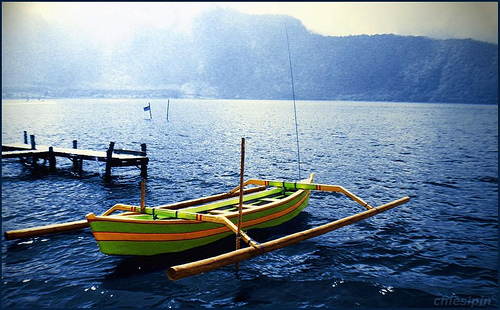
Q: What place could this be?
A: It is a lake.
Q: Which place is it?
A: It is a lake.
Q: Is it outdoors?
A: Yes, it is outdoors.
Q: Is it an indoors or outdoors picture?
A: It is outdoors.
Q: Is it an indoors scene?
A: No, it is outdoors.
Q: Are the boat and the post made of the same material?
A: Yes, both the boat and the post are made of wood.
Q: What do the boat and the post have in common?
A: The material, both the boat and the post are wooden.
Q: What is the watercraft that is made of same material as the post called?
A: The watercraft is a boat.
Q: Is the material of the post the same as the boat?
A: Yes, both the post and the boat are made of wood.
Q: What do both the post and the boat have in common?
A: The material, both the post and the boat are wooden.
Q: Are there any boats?
A: Yes, there is a boat.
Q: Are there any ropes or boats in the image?
A: Yes, there is a boat.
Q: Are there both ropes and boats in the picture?
A: No, there is a boat but no ropes.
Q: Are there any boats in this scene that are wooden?
A: Yes, there is a wood boat.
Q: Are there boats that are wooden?
A: Yes, there is a boat that is wooden.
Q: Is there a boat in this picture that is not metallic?
A: Yes, there is a wooden boat.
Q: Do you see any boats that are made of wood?
A: Yes, there is a boat that is made of wood.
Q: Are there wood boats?
A: Yes, there is a boat that is made of wood.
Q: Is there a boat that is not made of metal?
A: Yes, there is a boat that is made of wood.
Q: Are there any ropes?
A: No, there are no ropes.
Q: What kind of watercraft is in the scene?
A: The watercraft is a boat.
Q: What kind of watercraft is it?
A: The watercraft is a boat.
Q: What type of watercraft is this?
A: This is a boat.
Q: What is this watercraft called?
A: This is a boat.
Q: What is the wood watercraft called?
A: The watercraft is a boat.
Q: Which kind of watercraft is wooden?
A: The watercraft is a boat.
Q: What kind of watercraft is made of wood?
A: The watercraft is a boat.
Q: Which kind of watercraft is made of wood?
A: The watercraft is a boat.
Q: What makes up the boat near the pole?
A: The boat is made of wood.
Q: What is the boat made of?
A: The boat is made of wood.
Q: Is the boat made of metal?
A: No, the boat is made of wood.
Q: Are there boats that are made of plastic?
A: No, there is a boat but it is made of wood.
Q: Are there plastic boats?
A: No, there is a boat but it is made of wood.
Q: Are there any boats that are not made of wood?
A: No, there is a boat but it is made of wood.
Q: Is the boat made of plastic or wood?
A: The boat is made of wood.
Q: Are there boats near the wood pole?
A: Yes, there is a boat near the pole.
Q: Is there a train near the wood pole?
A: No, there is a boat near the pole.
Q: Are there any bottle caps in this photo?
A: No, there are no bottle caps.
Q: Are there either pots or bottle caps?
A: No, there are no bottle caps or pots.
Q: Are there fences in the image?
A: No, there are no fences.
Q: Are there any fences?
A: No, there are no fences.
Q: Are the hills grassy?
A: Yes, the hills are grassy.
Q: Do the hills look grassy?
A: Yes, the hills are grassy.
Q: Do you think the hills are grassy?
A: Yes, the hills are grassy.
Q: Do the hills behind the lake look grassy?
A: Yes, the hills are grassy.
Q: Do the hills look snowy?
A: No, the hills are grassy.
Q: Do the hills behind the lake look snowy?
A: No, the hills are grassy.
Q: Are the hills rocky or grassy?
A: The hills are grassy.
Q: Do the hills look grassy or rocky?
A: The hills are grassy.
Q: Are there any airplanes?
A: No, there are no airplanes.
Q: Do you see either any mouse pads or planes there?
A: No, there are no planes or mouse pads.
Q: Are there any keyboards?
A: No, there are no keyboards.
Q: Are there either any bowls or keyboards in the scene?
A: No, there are no keyboards or bowls.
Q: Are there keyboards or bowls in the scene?
A: No, there are no keyboards or bowls.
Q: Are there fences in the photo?
A: No, there are no fences.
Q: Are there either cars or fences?
A: No, there are no fences or cars.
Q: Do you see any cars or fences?
A: No, there are no fences or cars.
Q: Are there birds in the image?
A: No, there are no birds.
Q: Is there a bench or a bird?
A: No, there are no birds or benches.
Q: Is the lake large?
A: Yes, the lake is large.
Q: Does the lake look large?
A: Yes, the lake is large.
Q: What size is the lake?
A: The lake is large.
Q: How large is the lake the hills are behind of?
A: The lake is large.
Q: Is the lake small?
A: No, the lake is large.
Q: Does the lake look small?
A: No, the lake is large.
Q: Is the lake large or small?
A: The lake is large.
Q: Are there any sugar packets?
A: No, there are no sugar packets.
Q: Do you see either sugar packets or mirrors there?
A: No, there are no sugar packets or mirrors.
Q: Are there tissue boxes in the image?
A: No, there are no tissue boxes.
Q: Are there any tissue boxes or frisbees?
A: No, there are no tissue boxes or frisbees.